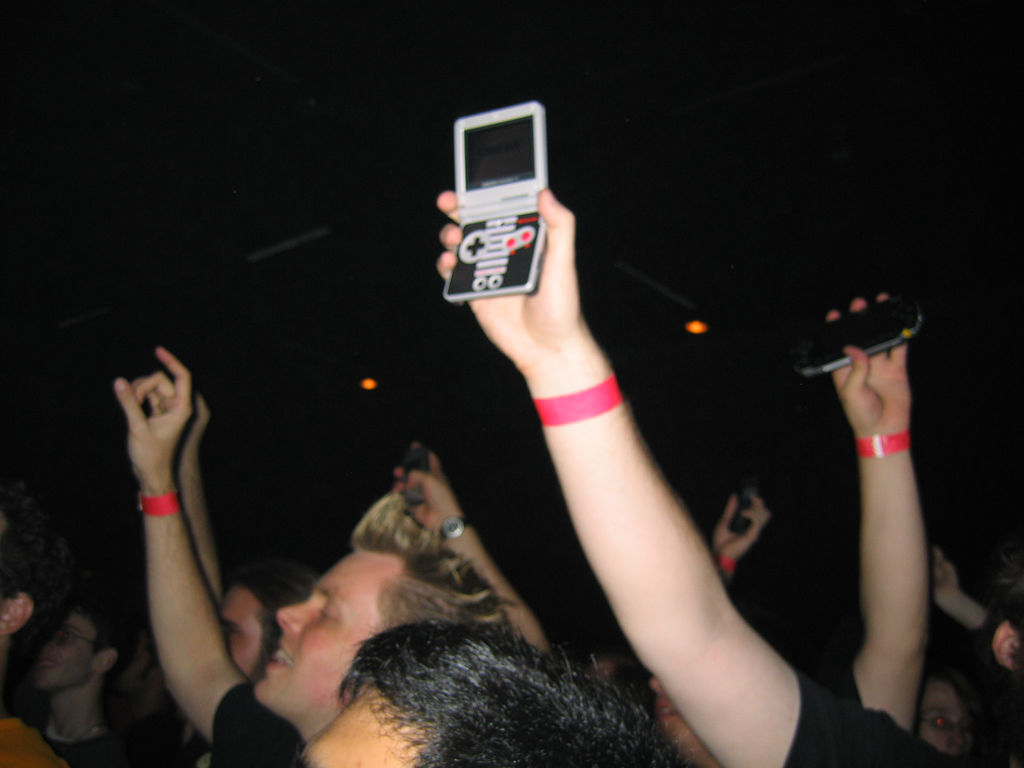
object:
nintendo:
[443, 100, 550, 303]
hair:
[350, 489, 520, 638]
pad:
[458, 229, 490, 264]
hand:
[435, 190, 582, 360]